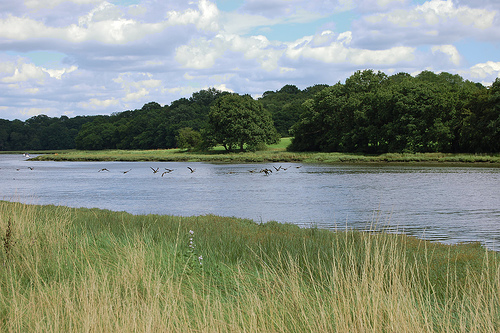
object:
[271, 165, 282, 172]
bird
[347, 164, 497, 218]
water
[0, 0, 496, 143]
sky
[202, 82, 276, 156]
tree